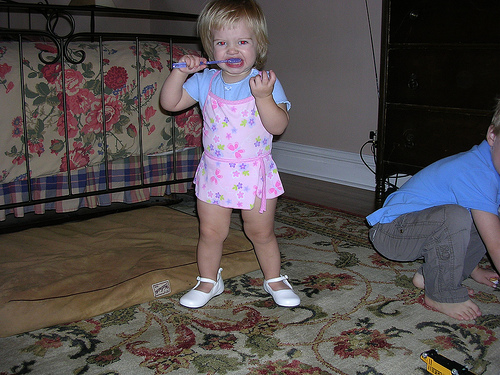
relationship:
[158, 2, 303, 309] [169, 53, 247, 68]
child holding toothbrush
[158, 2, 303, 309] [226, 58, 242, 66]
child brushing teeth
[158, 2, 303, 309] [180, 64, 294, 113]
child wearing shirt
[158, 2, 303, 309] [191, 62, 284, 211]
child wearing dress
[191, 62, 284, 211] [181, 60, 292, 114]
dress over shirt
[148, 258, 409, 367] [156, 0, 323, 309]
shoes worn by girl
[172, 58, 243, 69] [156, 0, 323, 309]
toothbrush held by girl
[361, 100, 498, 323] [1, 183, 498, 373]
boy on carpet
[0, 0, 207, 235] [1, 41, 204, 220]
frame on bed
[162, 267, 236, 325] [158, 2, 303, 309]
shoe on child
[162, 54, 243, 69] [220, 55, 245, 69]
toothbrush in mouth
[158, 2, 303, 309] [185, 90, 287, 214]
child wearing dress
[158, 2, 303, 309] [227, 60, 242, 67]
child brushing teeth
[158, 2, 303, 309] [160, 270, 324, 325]
child wearing shoes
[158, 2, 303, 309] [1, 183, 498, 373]
child standing on carpet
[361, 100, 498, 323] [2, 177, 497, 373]
boy standing on on rug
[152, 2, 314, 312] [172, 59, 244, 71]
child holding toothbrush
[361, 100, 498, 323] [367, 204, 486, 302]
boy wearing pants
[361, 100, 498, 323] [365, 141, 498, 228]
boy wearing shirt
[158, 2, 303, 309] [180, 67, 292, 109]
child wearing shirt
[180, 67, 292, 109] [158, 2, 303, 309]
shirt on child